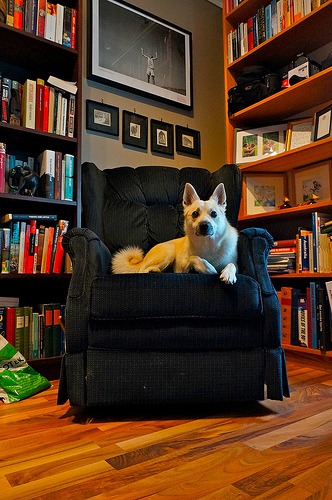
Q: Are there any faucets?
A: No, there are no faucets.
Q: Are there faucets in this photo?
A: No, there are no faucets.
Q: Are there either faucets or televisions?
A: No, there are no faucets or televisions.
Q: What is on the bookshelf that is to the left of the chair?
A: The books are on the bookshelf.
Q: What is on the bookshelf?
A: The books are on the bookshelf.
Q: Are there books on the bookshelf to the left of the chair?
A: Yes, there are books on the bookshelf.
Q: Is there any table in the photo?
A: No, there are no tables.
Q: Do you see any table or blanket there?
A: No, there are no tables or blankets.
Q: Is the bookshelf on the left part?
A: Yes, the bookshelf is on the left of the image.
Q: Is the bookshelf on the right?
A: No, the bookshelf is on the left of the image.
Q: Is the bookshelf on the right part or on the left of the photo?
A: The bookshelf is on the left of the image.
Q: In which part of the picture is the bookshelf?
A: The bookshelf is on the left of the image.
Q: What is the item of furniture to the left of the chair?
A: The piece of furniture is a bookshelf.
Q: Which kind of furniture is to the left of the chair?
A: The piece of furniture is a bookshelf.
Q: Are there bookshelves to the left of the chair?
A: Yes, there is a bookshelf to the left of the chair.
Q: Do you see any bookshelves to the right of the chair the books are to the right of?
A: No, the bookshelf is to the left of the chair.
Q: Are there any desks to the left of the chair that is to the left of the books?
A: No, there is a bookshelf to the left of the chair.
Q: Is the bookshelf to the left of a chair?
A: Yes, the bookshelf is to the left of a chair.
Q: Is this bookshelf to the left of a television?
A: No, the bookshelf is to the left of a chair.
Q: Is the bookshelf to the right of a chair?
A: No, the bookshelf is to the left of a chair.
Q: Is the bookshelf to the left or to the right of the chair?
A: The bookshelf is to the left of the chair.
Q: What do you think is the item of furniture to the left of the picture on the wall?
A: The piece of furniture is a bookshelf.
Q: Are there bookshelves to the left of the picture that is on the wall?
A: Yes, there is a bookshelf to the left of the picture.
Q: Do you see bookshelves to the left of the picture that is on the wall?
A: Yes, there is a bookshelf to the left of the picture.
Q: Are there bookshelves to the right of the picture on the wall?
A: No, the bookshelf is to the left of the picture.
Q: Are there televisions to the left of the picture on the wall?
A: No, there is a bookshelf to the left of the picture.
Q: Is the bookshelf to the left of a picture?
A: Yes, the bookshelf is to the left of a picture.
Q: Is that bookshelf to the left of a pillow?
A: No, the bookshelf is to the left of a picture.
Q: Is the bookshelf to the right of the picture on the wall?
A: No, the bookshelf is to the left of the picture.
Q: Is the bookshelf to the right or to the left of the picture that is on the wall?
A: The bookshelf is to the left of the picture.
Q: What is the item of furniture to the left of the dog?
A: The piece of furniture is a bookshelf.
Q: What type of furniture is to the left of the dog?
A: The piece of furniture is a bookshelf.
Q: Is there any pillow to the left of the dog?
A: No, there is a bookshelf to the left of the dog.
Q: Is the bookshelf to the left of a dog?
A: Yes, the bookshelf is to the left of a dog.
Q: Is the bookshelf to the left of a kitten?
A: No, the bookshelf is to the left of a dog.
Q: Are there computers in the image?
A: No, there are no computers.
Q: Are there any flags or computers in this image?
A: No, there are no computers or flags.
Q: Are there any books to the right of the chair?
A: Yes, there are books to the right of the chair.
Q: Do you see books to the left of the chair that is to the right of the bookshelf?
A: No, the books are to the right of the chair.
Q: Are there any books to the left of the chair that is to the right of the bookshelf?
A: No, the books are to the right of the chair.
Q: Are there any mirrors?
A: No, there are no mirrors.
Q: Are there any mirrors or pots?
A: No, there are no mirrors or pots.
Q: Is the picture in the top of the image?
A: Yes, the picture is in the top of the image.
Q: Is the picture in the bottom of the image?
A: No, the picture is in the top of the image.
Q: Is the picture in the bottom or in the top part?
A: The picture is in the top of the image.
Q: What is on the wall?
A: The picture is on the wall.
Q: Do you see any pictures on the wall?
A: Yes, there is a picture on the wall.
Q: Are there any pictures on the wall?
A: Yes, there is a picture on the wall.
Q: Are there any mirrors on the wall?
A: No, there is a picture on the wall.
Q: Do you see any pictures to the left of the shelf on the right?
A: Yes, there is a picture to the left of the shelf.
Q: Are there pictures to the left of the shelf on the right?
A: Yes, there is a picture to the left of the shelf.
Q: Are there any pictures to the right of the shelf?
A: No, the picture is to the left of the shelf.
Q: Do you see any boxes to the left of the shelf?
A: No, there is a picture to the left of the shelf.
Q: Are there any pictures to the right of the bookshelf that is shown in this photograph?
A: Yes, there is a picture to the right of the bookshelf.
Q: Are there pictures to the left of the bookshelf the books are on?
A: No, the picture is to the right of the bookshelf.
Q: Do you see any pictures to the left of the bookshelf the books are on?
A: No, the picture is to the right of the bookshelf.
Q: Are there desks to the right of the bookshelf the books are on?
A: No, there is a picture to the right of the bookshelf.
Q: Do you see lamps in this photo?
A: No, there are no lamps.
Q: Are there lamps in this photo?
A: No, there are no lamps.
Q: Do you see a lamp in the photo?
A: No, there are no lamps.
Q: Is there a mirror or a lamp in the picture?
A: No, there are no lamps or mirrors.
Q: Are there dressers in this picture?
A: No, there are no dressers.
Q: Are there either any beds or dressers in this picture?
A: No, there are no dressers or beds.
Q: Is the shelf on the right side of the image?
A: Yes, the shelf is on the right of the image.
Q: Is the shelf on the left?
A: No, the shelf is on the right of the image.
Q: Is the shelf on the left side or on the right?
A: The shelf is on the right of the image.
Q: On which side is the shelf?
A: The shelf is on the right of the image.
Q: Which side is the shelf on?
A: The shelf is on the right of the image.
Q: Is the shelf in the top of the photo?
A: Yes, the shelf is in the top of the image.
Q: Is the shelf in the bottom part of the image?
A: No, the shelf is in the top of the image.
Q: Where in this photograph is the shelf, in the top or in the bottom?
A: The shelf is in the top of the image.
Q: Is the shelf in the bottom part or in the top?
A: The shelf is in the top of the image.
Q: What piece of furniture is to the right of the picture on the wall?
A: The piece of furniture is a shelf.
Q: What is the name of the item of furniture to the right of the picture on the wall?
A: The piece of furniture is a shelf.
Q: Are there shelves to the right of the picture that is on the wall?
A: Yes, there is a shelf to the right of the picture.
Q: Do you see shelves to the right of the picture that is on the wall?
A: Yes, there is a shelf to the right of the picture.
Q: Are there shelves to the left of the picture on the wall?
A: No, the shelf is to the right of the picture.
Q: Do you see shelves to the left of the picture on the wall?
A: No, the shelf is to the right of the picture.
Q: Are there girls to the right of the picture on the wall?
A: No, there is a shelf to the right of the picture.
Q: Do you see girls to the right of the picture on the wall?
A: No, there is a shelf to the right of the picture.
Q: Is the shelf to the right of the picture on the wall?
A: Yes, the shelf is to the right of the picture.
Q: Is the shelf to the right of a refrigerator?
A: No, the shelf is to the right of the picture.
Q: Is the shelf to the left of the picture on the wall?
A: No, the shelf is to the right of the picture.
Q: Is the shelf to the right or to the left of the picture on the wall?
A: The shelf is to the right of the picture.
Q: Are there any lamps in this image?
A: No, there are no lamps.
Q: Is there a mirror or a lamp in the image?
A: No, there are no lamps or mirrors.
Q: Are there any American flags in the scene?
A: No, there are no American flags.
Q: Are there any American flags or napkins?
A: No, there are no American flags or napkins.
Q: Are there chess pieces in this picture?
A: No, there are no chess pieces.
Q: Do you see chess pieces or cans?
A: No, there are no chess pieces or cans.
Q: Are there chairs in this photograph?
A: Yes, there is a chair.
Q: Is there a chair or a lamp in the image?
A: Yes, there is a chair.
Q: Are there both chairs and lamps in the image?
A: No, there is a chair but no lamps.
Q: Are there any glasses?
A: No, there are no glasses.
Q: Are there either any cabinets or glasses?
A: No, there are no glasses or cabinets.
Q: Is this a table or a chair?
A: This is a chair.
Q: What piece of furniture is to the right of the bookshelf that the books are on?
A: The piece of furniture is a chair.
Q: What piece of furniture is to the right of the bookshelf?
A: The piece of furniture is a chair.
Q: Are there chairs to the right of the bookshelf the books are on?
A: Yes, there is a chair to the right of the bookshelf.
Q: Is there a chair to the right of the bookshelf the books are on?
A: Yes, there is a chair to the right of the bookshelf.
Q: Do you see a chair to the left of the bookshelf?
A: No, the chair is to the right of the bookshelf.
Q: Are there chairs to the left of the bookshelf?
A: No, the chair is to the right of the bookshelf.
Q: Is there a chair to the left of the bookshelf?
A: No, the chair is to the right of the bookshelf.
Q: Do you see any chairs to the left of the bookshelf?
A: No, the chair is to the right of the bookshelf.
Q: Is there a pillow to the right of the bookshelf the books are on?
A: No, there is a chair to the right of the bookshelf.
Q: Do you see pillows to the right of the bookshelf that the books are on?
A: No, there is a chair to the right of the bookshelf.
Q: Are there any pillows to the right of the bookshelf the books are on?
A: No, there is a chair to the right of the bookshelf.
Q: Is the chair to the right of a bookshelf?
A: Yes, the chair is to the right of a bookshelf.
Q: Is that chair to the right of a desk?
A: No, the chair is to the right of a bookshelf.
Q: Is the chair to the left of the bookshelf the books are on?
A: No, the chair is to the right of the bookshelf.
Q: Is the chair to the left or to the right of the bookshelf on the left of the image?
A: The chair is to the right of the bookshelf.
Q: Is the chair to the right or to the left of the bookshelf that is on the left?
A: The chair is to the right of the bookshelf.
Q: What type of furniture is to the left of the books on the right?
A: The piece of furniture is a chair.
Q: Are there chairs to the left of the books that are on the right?
A: Yes, there is a chair to the left of the books.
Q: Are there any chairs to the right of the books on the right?
A: No, the chair is to the left of the books.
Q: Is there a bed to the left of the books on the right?
A: No, there is a chair to the left of the books.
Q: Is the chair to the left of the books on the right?
A: Yes, the chair is to the left of the books.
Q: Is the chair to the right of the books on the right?
A: No, the chair is to the left of the books.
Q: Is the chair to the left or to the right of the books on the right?
A: The chair is to the left of the books.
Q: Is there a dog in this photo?
A: Yes, there is a dog.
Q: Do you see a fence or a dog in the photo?
A: Yes, there is a dog.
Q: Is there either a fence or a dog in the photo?
A: Yes, there is a dog.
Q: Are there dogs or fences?
A: Yes, there is a dog.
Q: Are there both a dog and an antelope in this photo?
A: No, there is a dog but no antelopes.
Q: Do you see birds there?
A: No, there are no birds.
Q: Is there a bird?
A: No, there are no birds.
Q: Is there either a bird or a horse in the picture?
A: No, there are no birds or horses.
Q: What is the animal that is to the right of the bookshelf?
A: The animal is a dog.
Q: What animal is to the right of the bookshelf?
A: The animal is a dog.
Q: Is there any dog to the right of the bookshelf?
A: Yes, there is a dog to the right of the bookshelf.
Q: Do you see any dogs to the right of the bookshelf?
A: Yes, there is a dog to the right of the bookshelf.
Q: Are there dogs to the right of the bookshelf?
A: Yes, there is a dog to the right of the bookshelf.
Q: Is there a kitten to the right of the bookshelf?
A: No, there is a dog to the right of the bookshelf.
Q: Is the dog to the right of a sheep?
A: No, the dog is to the right of the bookshelf.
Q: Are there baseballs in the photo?
A: No, there are no baseballs.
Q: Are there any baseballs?
A: No, there are no baseballs.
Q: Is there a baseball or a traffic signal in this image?
A: No, there are no baseballs or traffic lights.